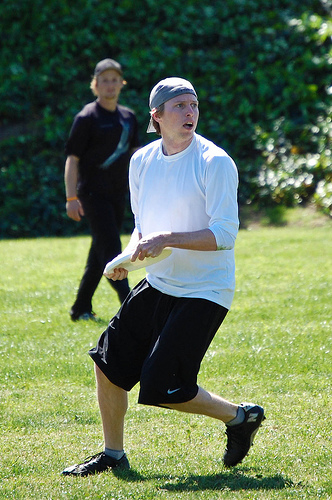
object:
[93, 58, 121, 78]
cap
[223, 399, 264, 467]
shoe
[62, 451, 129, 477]
shoe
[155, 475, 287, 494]
shadow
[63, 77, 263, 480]
male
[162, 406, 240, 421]
shin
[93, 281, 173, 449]
leg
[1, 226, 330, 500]
grass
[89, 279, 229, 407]
shorts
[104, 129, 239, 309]
shirt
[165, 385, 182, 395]
nike swoosh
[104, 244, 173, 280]
frisbee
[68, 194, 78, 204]
wristband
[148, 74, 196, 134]
hat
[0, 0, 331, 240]
tree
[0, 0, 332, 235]
foliage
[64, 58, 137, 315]
player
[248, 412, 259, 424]
sign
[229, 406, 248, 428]
sock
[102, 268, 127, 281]
hand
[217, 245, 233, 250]
stain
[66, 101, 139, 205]
shirt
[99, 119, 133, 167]
design